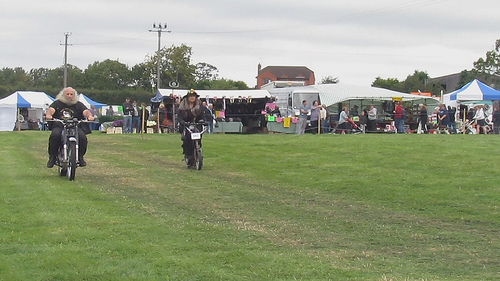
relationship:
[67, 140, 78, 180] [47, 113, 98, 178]
wheel in bike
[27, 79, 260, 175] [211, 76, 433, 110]
men in tents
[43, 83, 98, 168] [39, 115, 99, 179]
man on motorcycle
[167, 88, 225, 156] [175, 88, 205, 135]
person wearing jacket